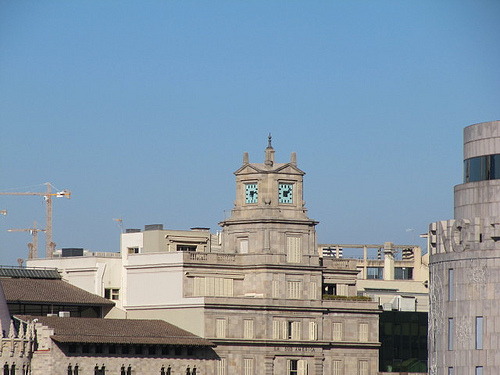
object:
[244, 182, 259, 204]
clock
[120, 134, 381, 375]
building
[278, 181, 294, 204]
clock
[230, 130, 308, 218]
tower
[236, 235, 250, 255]
window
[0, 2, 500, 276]
sky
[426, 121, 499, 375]
buildings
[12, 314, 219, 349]
roof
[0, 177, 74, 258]
crane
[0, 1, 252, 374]
left